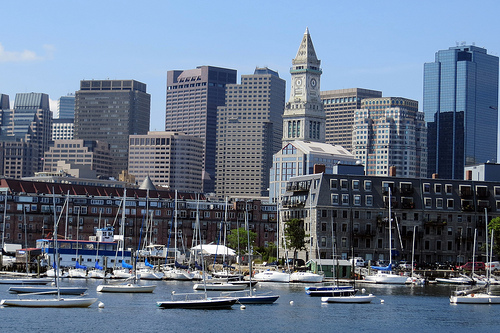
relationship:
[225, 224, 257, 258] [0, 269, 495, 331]
palm tree in water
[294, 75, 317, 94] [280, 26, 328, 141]
clock on top of tower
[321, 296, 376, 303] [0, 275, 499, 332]
boat in ocean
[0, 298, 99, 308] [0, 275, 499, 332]
boat in ocean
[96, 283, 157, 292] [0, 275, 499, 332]
boat in ocean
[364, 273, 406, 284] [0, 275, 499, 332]
boat in ocean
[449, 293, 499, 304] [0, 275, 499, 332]
boat in ocean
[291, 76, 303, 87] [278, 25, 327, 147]
clock on building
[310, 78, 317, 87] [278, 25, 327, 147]
clock on building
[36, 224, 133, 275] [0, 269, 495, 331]
boat on water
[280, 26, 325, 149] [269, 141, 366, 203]
clocktower on top of building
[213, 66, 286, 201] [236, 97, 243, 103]
building with window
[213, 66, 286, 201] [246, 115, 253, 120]
building with window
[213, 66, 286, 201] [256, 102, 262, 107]
building with window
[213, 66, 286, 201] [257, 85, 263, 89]
building with window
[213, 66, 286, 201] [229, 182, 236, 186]
building with window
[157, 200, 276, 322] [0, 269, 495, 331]
object in water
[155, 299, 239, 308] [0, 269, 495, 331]
boat in water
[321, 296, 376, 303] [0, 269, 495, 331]
boat in water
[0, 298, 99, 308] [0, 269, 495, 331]
boat in water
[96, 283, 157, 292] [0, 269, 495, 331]
boat in water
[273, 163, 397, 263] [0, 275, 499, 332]
building near ocean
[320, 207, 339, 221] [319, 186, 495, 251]
window on building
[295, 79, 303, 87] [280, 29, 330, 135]
clock on tower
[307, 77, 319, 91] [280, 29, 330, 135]
clock on tower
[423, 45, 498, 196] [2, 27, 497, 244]
building in city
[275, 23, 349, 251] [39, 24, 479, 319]
clocktower in city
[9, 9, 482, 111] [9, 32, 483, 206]
sky above buildings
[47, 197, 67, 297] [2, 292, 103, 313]
pole on boat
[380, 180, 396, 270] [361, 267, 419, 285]
pole on boat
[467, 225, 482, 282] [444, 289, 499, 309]
pole on boat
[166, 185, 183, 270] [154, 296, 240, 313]
pole on boat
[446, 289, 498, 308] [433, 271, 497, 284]
boat next boat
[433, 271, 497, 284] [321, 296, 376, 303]
boat next boat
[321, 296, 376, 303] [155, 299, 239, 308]
boat next boat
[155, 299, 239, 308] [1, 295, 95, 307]
boat next boat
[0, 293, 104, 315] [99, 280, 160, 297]
boat next boat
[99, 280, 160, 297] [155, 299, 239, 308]
boat next boat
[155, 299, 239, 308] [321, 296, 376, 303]
boat next boat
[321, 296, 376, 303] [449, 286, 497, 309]
boat next boat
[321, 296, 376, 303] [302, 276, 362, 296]
boat next boat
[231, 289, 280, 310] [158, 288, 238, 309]
boat next to boat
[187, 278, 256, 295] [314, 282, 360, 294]
boat next to boat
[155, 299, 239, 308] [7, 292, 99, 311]
boat next to boat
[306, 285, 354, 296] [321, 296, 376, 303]
boat next to boat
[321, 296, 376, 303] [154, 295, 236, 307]
boat next to boat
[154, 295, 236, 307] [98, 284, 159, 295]
boat next to boat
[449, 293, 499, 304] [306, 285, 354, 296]
boat next to boat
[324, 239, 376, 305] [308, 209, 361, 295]
boat next to boat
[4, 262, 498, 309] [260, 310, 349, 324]
boats in water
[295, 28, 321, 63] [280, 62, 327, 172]
steeple on tower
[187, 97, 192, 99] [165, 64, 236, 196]
windows on side of building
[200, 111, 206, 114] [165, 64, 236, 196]
windows on side of building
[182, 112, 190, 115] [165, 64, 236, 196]
windows on side of building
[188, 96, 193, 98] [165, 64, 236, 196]
windows on side of building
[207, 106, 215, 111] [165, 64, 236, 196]
windows on side of building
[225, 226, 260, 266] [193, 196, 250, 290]
palm tree by boat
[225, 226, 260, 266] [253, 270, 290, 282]
palm tree by boat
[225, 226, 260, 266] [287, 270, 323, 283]
palm tree by boat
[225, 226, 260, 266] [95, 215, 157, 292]
palm tree by boat